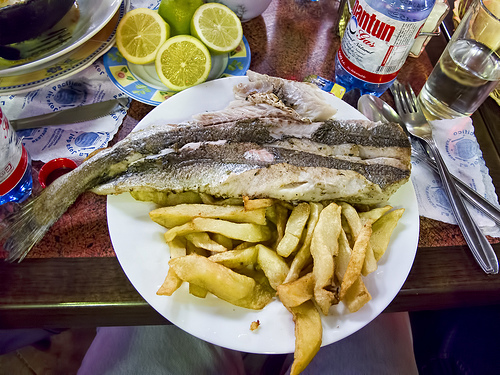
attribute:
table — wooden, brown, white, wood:
[37, 242, 113, 307]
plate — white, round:
[202, 86, 224, 106]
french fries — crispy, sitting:
[209, 210, 345, 286]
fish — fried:
[156, 107, 376, 182]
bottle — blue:
[335, 8, 424, 75]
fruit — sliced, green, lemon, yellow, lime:
[121, 2, 222, 73]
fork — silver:
[396, 88, 459, 160]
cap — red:
[30, 155, 72, 182]